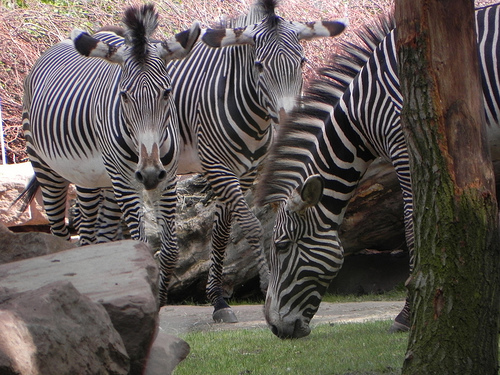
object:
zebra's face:
[252, 21, 305, 118]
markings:
[274, 47, 288, 72]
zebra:
[6, 2, 201, 315]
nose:
[132, 155, 168, 187]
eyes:
[116, 87, 137, 100]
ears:
[201, 24, 259, 49]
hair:
[226, 73, 233, 100]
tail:
[9, 177, 39, 216]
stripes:
[70, 90, 77, 128]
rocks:
[0, 278, 130, 375]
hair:
[248, 1, 277, 21]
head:
[68, 3, 200, 191]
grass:
[170, 316, 410, 375]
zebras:
[259, 3, 499, 338]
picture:
[0, 0, 498, 374]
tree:
[389, 0, 498, 374]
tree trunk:
[390, 1, 499, 375]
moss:
[442, 193, 491, 259]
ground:
[163, 290, 426, 373]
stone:
[160, 303, 212, 327]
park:
[0, 0, 497, 374]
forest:
[0, 0, 390, 163]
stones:
[0, 239, 162, 373]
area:
[155, 318, 409, 373]